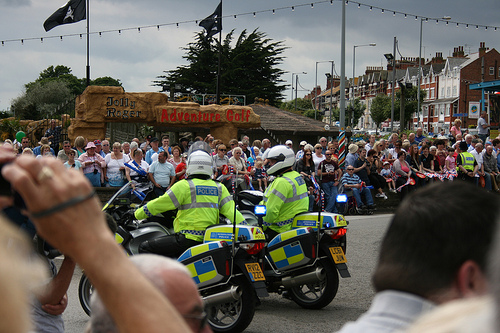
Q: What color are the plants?
A: Green.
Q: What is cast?
A: Shadow.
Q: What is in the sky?
A: Clouds.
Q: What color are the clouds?
A: Grey.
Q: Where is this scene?
A: Street.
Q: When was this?
A: Daytime.